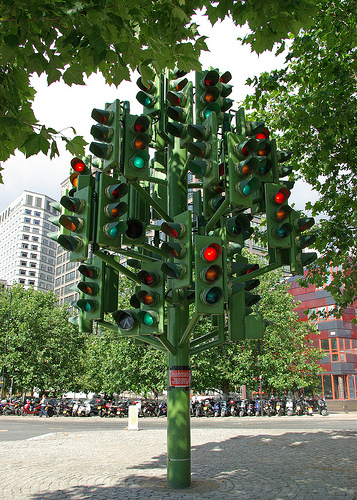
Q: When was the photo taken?
A: Daytime.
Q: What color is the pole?
A: Green.